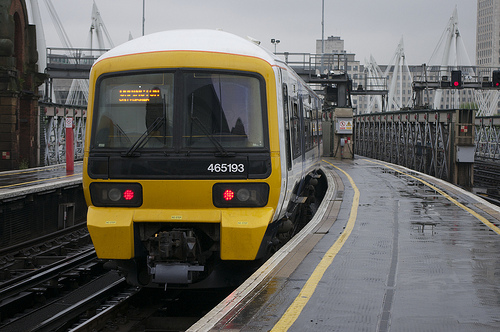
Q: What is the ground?
A: Wet.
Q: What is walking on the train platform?
A: No one is walking.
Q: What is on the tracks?
A: The train.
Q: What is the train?
A: Grey and yellow.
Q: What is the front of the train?
A: Yellow.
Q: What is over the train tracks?
A: The metal bridge.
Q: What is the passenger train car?
A: Yellow.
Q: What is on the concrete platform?
A: Puddles.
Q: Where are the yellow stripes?
A: On the platform.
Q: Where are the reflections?
A: In the train windows.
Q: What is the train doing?
A: Running.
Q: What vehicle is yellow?
A: The train.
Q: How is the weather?
A: Rainy.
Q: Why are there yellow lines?
A: For safety.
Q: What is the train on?
A: The tracks.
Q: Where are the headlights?
A: In the train.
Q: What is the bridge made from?
A: Metal.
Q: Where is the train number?
A: On the front.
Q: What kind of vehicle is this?
A: Train.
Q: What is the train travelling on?
A: Train tracks.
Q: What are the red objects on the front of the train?
A: Headlights.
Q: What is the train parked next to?
A: Platform.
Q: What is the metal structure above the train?
A: Bridge.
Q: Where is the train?
A: Next to platform.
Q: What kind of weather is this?
A: Rain.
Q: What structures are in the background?
A: City buildings.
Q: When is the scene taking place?
A: Daytime.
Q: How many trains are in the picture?
A: One.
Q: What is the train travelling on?
A: Train tracks.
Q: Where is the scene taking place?
A: On the train tracks.